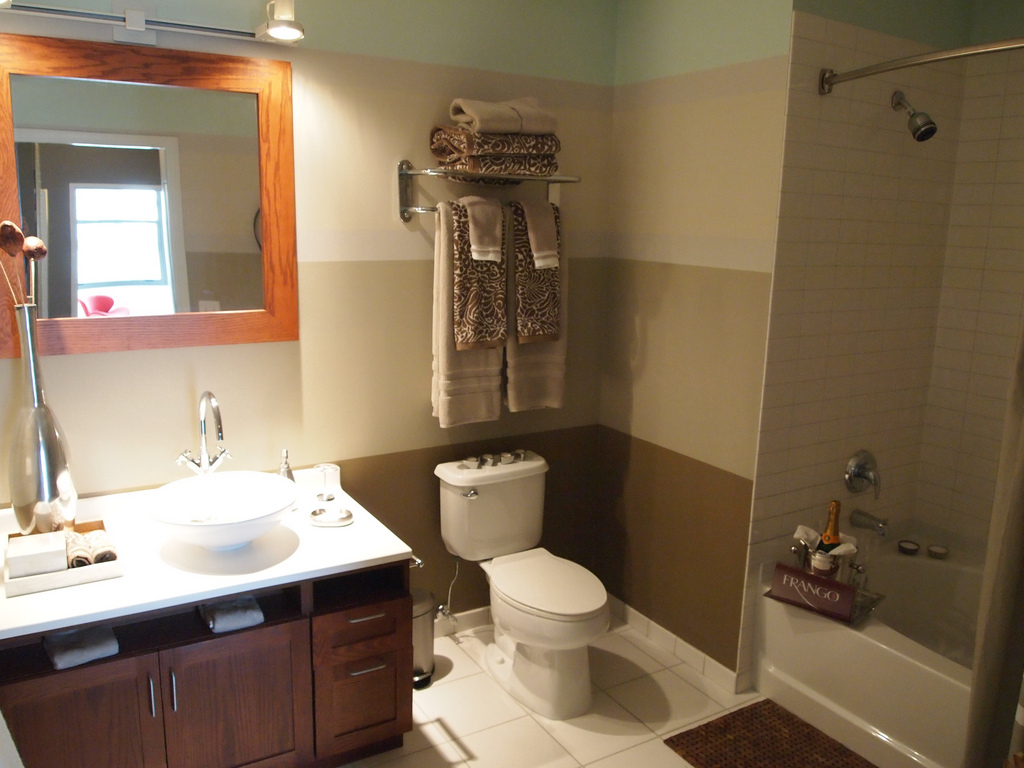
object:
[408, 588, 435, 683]
trash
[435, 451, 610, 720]
toilet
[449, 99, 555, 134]
towel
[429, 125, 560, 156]
towel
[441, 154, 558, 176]
towel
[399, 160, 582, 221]
rack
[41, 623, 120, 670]
towel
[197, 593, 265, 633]
towel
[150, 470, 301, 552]
sink